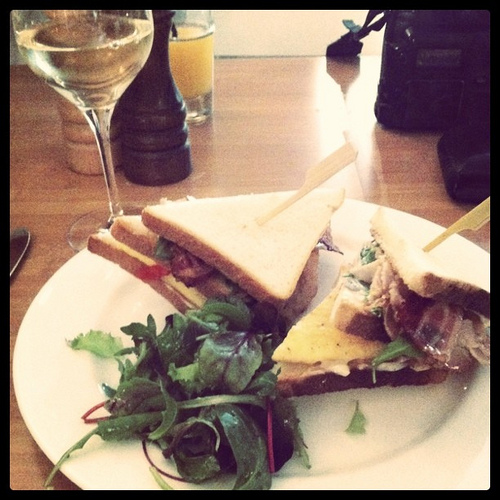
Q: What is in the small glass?
A: Orange juice.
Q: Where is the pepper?
A: On table.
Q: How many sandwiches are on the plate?
A: 2.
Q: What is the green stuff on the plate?
A: Salad.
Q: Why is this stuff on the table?
A: Lunch.